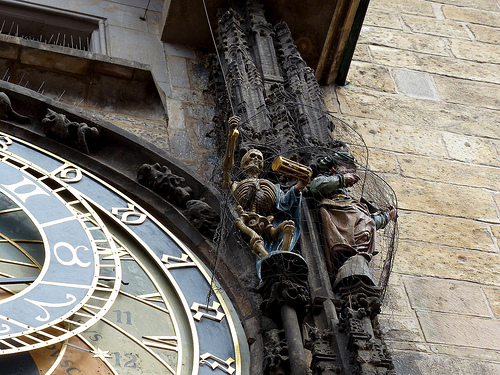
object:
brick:
[414, 307, 499, 351]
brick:
[380, 272, 415, 315]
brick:
[375, 313, 423, 343]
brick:
[388, 350, 500, 374]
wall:
[0, 0, 500, 375]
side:
[397, 73, 440, 105]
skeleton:
[219, 115, 313, 269]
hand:
[300, 166, 312, 187]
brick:
[402, 273, 492, 320]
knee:
[276, 210, 308, 247]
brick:
[381, 171, 498, 223]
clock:
[0, 125, 257, 375]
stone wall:
[328, 0, 498, 374]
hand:
[227, 115, 242, 136]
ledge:
[0, 30, 176, 128]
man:
[312, 151, 397, 296]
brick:
[389, 67, 441, 101]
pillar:
[204, 10, 398, 375]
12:
[108, 350, 138, 370]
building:
[0, 0, 499, 372]